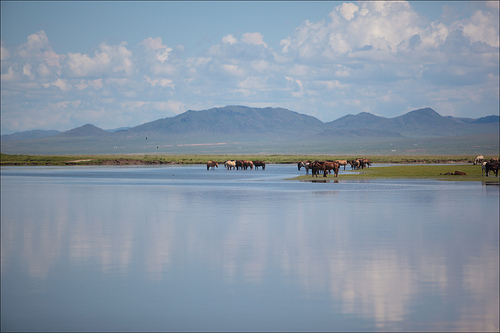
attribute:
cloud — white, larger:
[312, 12, 401, 67]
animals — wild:
[212, 153, 274, 173]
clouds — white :
[1, 2, 498, 104]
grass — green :
[328, 137, 457, 193]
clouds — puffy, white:
[39, 24, 382, 96]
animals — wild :
[204, 154, 278, 169]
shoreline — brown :
[104, 156, 161, 165]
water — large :
[6, 176, 496, 332]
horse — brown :
[309, 156, 343, 178]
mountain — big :
[170, 77, 457, 204]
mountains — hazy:
[1, 104, 499, 156]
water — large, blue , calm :
[2, 161, 499, 331]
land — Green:
[101, 149, 181, 166]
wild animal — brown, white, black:
[483, 160, 498, 178]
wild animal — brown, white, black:
[472, 155, 487, 166]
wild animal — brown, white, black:
[361, 155, 373, 168]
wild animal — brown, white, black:
[347, 157, 360, 168]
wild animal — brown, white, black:
[337, 157, 350, 170]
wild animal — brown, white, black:
[316, 161, 339, 178]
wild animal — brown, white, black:
[296, 159, 312, 174]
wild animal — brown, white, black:
[251, 158, 266, 169]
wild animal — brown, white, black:
[241, 159, 253, 171]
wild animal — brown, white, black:
[224, 160, 236, 174]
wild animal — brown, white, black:
[204, 159, 220, 171]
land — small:
[0, 105, 499, 182]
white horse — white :
[221, 154, 239, 172]